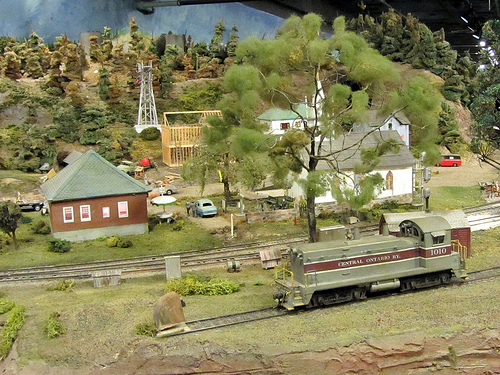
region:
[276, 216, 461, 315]
the train is green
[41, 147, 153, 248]
the house is brown and green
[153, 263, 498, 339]
the train is on the tracks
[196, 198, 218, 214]
the car is blue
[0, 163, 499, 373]
the ground is green and brown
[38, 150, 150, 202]
the top of the house is green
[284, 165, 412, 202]
the church is white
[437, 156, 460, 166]
the car is red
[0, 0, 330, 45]
the sky is dark blue and cloudy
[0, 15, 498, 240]
many trees scattered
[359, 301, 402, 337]
part of a ground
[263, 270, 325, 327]
part of a train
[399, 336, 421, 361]
edge of a stone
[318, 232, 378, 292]
edge of a train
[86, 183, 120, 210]
edge of a roof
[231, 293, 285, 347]
part of a rail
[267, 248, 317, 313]
part of a train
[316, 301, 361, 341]
part of a ground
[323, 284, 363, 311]
part of a wheel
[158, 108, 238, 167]
the wooden frame of an unfinished building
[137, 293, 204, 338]
end of a railroad track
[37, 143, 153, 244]
a brown house with green trim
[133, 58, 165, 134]
a steel communication tower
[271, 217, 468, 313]
a green and brown train with no boxcars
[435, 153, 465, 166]
a small red car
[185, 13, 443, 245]
a large single tree near train track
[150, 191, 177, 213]
lime green table umbrella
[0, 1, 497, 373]
scale model of a train and small town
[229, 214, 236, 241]
a white wooden post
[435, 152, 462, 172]
the car is small and red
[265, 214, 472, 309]
the model train is green and rust colored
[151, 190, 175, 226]
patio table with an umbrella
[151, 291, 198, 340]
brown stone at the end of tracks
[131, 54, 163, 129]
white model radio tower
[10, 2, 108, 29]
painted blue sky in the back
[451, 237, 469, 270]
tain has yellow rails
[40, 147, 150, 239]
small toy house with green roof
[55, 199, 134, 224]
side of toy house has four windows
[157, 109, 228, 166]
wooden frame of a model toy house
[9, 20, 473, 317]
a view of a town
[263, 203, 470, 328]
a parked train on the track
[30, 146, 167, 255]
a brown house in the area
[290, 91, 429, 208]
a white church in the scene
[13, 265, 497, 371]
this ground is sparse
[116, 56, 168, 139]
a white tower ner the hill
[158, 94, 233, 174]
an unfinished house being constructed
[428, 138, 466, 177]
a parked red car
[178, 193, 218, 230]
a blue car in the driveway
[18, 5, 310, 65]
asome blue obejct in the background